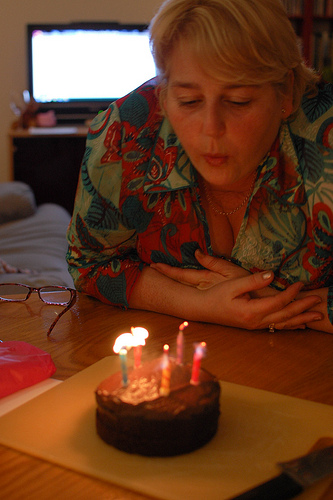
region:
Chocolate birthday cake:
[91, 321, 223, 460]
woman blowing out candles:
[166, 61, 276, 190]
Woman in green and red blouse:
[106, 5, 331, 205]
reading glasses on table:
[1, 270, 82, 342]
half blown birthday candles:
[97, 314, 215, 410]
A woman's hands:
[130, 248, 332, 340]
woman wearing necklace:
[146, 86, 308, 221]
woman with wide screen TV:
[19, 14, 300, 184]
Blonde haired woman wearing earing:
[139, 1, 326, 196]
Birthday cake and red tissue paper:
[0, 317, 225, 459]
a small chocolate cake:
[95, 357, 223, 459]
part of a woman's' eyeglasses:
[0, 279, 79, 338]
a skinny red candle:
[187, 350, 203, 384]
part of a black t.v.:
[27, 19, 156, 108]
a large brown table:
[1, 278, 327, 498]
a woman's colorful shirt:
[66, 73, 331, 314]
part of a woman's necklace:
[203, 180, 252, 218]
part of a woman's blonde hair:
[145, 0, 318, 114]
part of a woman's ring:
[266, 320, 276, 335]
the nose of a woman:
[201, 97, 226, 136]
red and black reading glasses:
[1, 272, 79, 329]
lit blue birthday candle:
[110, 334, 135, 378]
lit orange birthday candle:
[129, 324, 153, 366]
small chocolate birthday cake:
[100, 364, 238, 443]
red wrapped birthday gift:
[4, 340, 61, 380]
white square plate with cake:
[19, 342, 331, 496]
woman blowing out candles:
[179, 137, 256, 178]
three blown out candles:
[157, 316, 220, 399]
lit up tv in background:
[12, 19, 169, 103]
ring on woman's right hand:
[256, 316, 288, 332]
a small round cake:
[82, 190, 309, 497]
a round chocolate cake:
[71, 327, 244, 475]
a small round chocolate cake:
[101, 321, 280, 450]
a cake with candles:
[67, 307, 292, 481]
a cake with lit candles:
[106, 300, 242, 460]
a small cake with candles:
[70, 313, 242, 489]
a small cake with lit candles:
[85, 311, 295, 497]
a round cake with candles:
[72, 308, 239, 497]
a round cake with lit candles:
[85, 307, 229, 456]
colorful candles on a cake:
[112, 321, 202, 396]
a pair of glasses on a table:
[1, 280, 76, 336]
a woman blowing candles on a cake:
[145, 1, 320, 186]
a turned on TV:
[25, 25, 154, 106]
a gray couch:
[0, 181, 73, 296]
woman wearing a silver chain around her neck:
[195, 173, 255, 217]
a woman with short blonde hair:
[147, 3, 317, 186]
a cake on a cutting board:
[2, 352, 331, 498]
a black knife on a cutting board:
[220, 443, 330, 498]